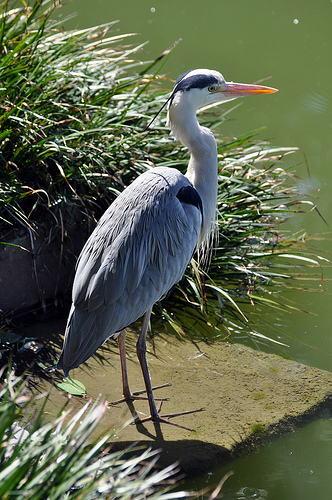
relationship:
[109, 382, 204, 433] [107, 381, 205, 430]
talons on feet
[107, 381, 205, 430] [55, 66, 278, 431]
feet on bird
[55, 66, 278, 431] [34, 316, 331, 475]
bird on cement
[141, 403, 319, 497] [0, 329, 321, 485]
water by shore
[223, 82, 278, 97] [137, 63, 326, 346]
beak on bird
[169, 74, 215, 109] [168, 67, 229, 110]
streak on head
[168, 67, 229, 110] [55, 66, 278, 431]
head on bird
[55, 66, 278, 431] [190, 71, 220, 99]
bird has eye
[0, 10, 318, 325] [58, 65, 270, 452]
bush behind bird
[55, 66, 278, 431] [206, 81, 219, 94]
bird has eye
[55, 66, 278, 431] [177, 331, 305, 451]
bird on stone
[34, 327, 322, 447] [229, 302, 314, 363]
concrete in water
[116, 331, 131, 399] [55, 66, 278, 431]
left leg on bird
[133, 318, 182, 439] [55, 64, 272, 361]
leg on bird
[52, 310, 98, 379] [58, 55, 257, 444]
tail on bird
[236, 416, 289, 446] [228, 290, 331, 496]
edge on shore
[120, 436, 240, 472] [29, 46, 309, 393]
shadow of bird